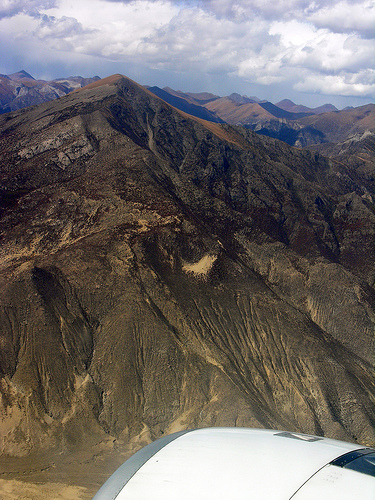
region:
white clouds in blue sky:
[12, 7, 43, 34]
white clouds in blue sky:
[103, 14, 126, 29]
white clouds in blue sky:
[229, 37, 257, 63]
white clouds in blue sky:
[301, 22, 332, 59]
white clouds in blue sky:
[146, 11, 184, 62]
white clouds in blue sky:
[216, 17, 246, 78]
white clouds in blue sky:
[75, 22, 124, 48]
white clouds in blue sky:
[135, 29, 175, 55]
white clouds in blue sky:
[295, 39, 332, 60]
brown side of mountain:
[126, 164, 207, 211]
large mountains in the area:
[25, 68, 323, 329]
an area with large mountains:
[31, 50, 374, 413]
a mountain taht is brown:
[49, 43, 368, 316]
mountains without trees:
[49, 100, 310, 428]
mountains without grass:
[59, 196, 371, 421]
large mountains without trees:
[54, 170, 367, 431]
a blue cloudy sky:
[53, 7, 278, 94]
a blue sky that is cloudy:
[133, 4, 369, 157]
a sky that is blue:
[107, 9, 370, 121]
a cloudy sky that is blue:
[145, 9, 359, 107]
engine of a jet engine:
[102, 404, 374, 495]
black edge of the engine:
[80, 406, 192, 490]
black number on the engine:
[279, 412, 328, 454]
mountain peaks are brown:
[65, 58, 357, 154]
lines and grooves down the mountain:
[182, 269, 322, 407]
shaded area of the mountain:
[22, 250, 92, 346]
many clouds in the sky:
[43, 4, 363, 92]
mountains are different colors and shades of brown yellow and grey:
[150, 62, 319, 150]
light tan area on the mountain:
[181, 249, 222, 283]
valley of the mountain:
[18, 428, 114, 477]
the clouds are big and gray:
[63, 17, 322, 92]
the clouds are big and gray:
[107, 8, 315, 68]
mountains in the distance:
[150, 80, 294, 141]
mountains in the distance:
[2, 58, 122, 118]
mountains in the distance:
[143, 53, 364, 151]